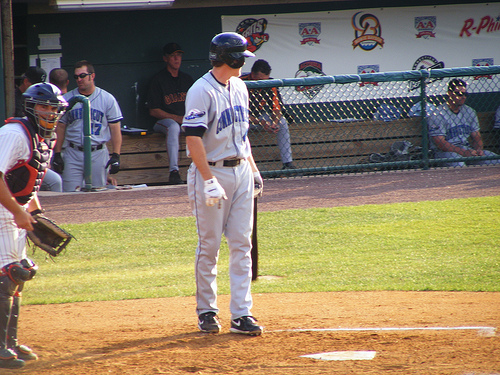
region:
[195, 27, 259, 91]
Black helmet on batter's head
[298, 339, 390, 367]
Home plate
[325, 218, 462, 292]
Green grass on the field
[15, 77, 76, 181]
Catcher wearing a face mask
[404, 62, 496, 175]
Player sitting in the dugout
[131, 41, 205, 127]
Player wearing a black hat and shirt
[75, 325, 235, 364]
Batter's shadow on the dirt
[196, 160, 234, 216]
White glove worn by the batter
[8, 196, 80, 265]
Baseball glove held by the catcher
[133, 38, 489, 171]
Players sitting on a brown bench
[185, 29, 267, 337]
Player in gray uniform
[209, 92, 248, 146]
Blue writing on uniform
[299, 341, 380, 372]
White base on home mound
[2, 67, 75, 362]
Catcher behind hitter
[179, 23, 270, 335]
man holding black bat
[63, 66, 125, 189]
man in dugout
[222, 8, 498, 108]
Logo's on wall banner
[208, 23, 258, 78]
Blue helmet on man's head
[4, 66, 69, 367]
Catcher has on safety equipment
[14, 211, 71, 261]
Glove on catcher's hand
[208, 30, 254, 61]
black plastic batting helmet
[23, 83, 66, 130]
black plastic catchers helmet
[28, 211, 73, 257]
brown leather catchers mitt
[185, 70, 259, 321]
blue and white baseball uniform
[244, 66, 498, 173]
metal chain link fence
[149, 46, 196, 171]
man sitting on bench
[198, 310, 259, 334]
black and white cleats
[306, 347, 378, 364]
white rubber home plate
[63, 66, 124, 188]
man standing in dugout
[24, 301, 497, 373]
dirt around home plate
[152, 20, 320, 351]
baseball player at bat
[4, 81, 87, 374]
catcher standing on dirt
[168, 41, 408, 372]
dugout behind home plate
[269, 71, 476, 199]
green fencing in front of dugout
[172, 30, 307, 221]
baseball player wearing gray uniform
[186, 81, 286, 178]
blue writing on gray uniform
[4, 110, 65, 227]
red and black padding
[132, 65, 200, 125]
black and orange shirt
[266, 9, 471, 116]
banner on dugout wall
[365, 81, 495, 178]
baseball player sitting in dugout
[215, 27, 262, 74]
the helmet is black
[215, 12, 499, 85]
the banner is white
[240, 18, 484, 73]
logos on the banner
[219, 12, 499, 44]
banner on the wall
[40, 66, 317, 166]
players in the dugout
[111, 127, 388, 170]
the bench is wooden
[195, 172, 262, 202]
the gloves are white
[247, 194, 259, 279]
the bat is black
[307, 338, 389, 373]
the baseball diamond is white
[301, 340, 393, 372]
the diamond is in dirt